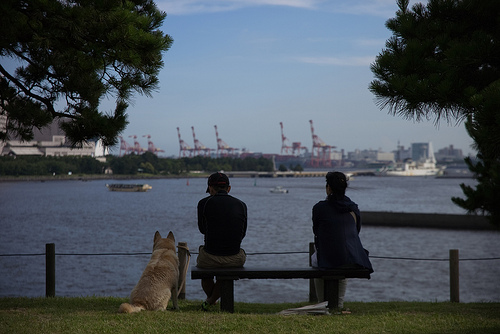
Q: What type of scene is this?
A: Outdoor.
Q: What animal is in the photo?
A: Dog.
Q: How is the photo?
A: Clear.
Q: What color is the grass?
A: Green.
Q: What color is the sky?
A: Blue.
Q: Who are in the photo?
A: People.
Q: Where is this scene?
A: Near water body.